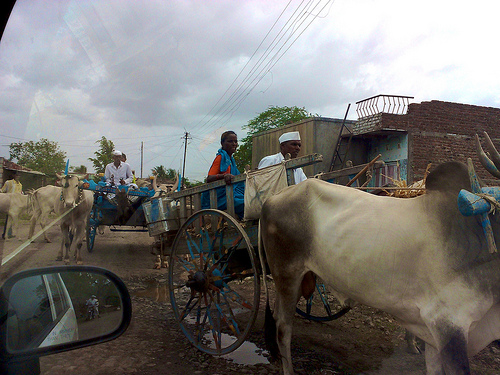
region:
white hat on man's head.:
[278, 129, 303, 142]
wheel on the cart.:
[183, 227, 235, 323]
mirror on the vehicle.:
[23, 264, 123, 346]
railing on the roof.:
[362, 89, 407, 111]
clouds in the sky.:
[92, 32, 178, 73]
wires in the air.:
[263, 15, 297, 79]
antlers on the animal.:
[472, 142, 492, 179]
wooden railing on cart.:
[185, 181, 241, 208]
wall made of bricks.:
[435, 112, 473, 124]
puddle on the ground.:
[232, 346, 262, 360]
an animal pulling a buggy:
[92, 10, 497, 345]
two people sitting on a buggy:
[141, 90, 435, 332]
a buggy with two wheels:
[104, 122, 496, 344]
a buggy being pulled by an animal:
[122, 102, 485, 354]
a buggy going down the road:
[121, 71, 441, 364]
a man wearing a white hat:
[262, 89, 376, 249]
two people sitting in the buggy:
[176, 75, 479, 313]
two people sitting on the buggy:
[166, 73, 491, 280]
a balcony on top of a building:
[314, 45, 475, 161]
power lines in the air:
[114, 52, 421, 184]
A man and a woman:
[178, 119, 330, 258]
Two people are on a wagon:
[195, 115, 315, 235]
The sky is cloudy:
[0, 1, 497, 146]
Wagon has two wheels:
[160, 201, 366, 361]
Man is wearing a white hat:
[268, 123, 311, 150]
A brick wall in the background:
[395, 96, 495, 171]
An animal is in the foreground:
[255, 130, 495, 370]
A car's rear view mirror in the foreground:
[5, 251, 135, 368]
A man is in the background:
[97, 142, 138, 212]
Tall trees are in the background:
[6, 132, 118, 179]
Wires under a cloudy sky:
[141, 2, 373, 94]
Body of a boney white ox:
[255, 131, 496, 371]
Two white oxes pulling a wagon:
[55, 166, 185, 262]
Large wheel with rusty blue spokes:
[161, 201, 261, 358]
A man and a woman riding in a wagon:
[191, 125, 326, 252]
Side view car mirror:
[6, 258, 138, 372]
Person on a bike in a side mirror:
[80, 259, 141, 349]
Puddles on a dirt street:
[108, 254, 282, 371]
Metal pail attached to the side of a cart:
[141, 164, 246, 309]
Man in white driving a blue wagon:
[56, 145, 143, 247]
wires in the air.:
[246, 25, 286, 87]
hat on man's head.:
[280, 130, 299, 139]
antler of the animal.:
[468, 167, 493, 204]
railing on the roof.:
[365, 95, 406, 107]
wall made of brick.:
[409, 115, 466, 131]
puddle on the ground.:
[227, 343, 262, 372]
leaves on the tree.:
[27, 150, 57, 160]